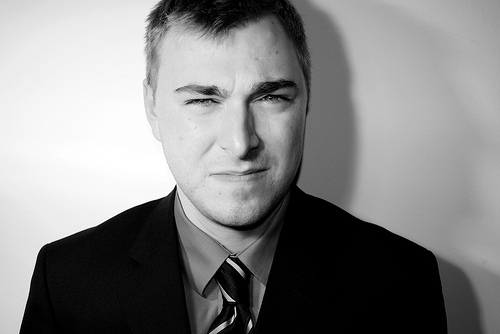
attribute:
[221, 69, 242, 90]
line — frown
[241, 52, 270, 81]
line — frown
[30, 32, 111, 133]
wall — white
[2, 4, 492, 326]
photograph — white, black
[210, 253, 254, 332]
tie — striped, complete, straight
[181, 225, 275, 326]
shirt — grey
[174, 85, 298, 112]
eyes — squinted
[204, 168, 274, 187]
lips — closed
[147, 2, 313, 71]
hair — short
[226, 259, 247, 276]
stripe — white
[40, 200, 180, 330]
jacket — black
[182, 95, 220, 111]
eye — squinted